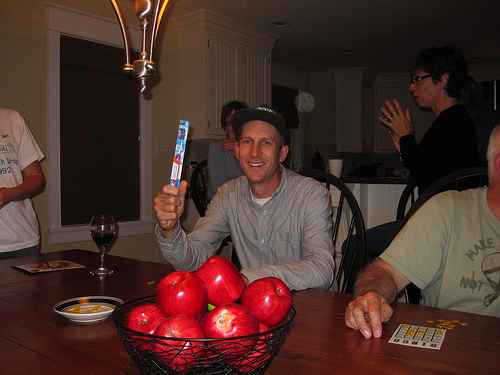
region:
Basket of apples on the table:
[100, 202, 308, 367]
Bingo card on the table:
[353, 265, 485, 373]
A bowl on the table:
[30, 272, 132, 347]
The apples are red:
[72, 250, 302, 370]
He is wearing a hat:
[209, 85, 283, 267]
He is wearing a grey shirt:
[173, 159, 323, 294]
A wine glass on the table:
[67, 196, 130, 285]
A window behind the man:
[24, 10, 159, 252]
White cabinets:
[162, 17, 288, 144]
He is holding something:
[155, 102, 200, 258]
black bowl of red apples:
[111, 255, 296, 374]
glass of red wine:
[85, 213, 120, 276]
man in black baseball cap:
[156, 106, 338, 290]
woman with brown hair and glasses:
[376, 53, 488, 200]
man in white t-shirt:
[0, 103, 47, 254]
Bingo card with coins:
[386, 319, 448, 354]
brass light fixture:
[118, 28, 164, 97]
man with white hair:
[346, 116, 498, 341]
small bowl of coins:
[53, 296, 123, 323]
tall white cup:
[327, 158, 344, 181]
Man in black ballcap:
[215, 99, 326, 259]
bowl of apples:
[108, 238, 327, 370]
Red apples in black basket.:
[112, 233, 319, 373]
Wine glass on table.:
[86, 206, 150, 298]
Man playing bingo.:
[343, 110, 499, 367]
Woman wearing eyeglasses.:
[374, 25, 481, 198]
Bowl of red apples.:
[103, 253, 318, 373]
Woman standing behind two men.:
[158, 34, 498, 284]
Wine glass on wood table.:
[30, 193, 122, 292]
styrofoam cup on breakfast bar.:
[320, 146, 397, 251]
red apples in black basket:
[107, 254, 299, 371]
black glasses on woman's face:
[406, 70, 441, 80]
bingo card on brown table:
[385, 316, 450, 346]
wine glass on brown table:
[82, 210, 118, 275]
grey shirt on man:
[147, 170, 333, 280]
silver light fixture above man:
[100, 0, 165, 96]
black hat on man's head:
[225, 105, 291, 140]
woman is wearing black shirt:
[380, 36, 480, 201]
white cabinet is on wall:
[170, 7, 275, 137]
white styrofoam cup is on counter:
[320, 151, 351, 181]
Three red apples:
[155, 255, 290, 321]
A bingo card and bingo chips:
[387, 315, 475, 352]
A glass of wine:
[86, 214, 121, 276]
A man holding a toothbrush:
[151, 105, 339, 293]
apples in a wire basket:
[117, 255, 299, 372]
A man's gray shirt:
[155, 169, 338, 290]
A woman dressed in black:
[340, 46, 487, 298]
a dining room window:
[47, 1, 160, 244]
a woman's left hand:
[380, 95, 414, 137]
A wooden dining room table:
[0, 250, 495, 373]